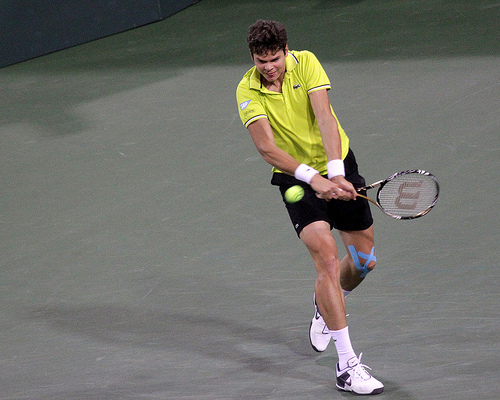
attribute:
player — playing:
[231, 17, 310, 113]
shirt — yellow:
[227, 78, 343, 168]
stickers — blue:
[347, 242, 371, 284]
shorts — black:
[280, 177, 376, 230]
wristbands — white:
[293, 157, 347, 191]